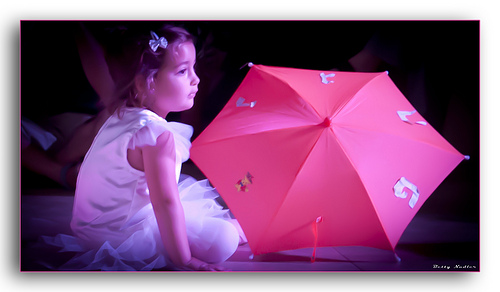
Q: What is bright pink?
A: Umbrella.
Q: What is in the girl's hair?
A: Barrette.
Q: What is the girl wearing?
A: Tutu.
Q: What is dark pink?
A: Umbrella.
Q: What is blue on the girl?
A: Hair ribbon.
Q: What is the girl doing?
A: Sitting.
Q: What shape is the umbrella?
A: Hexagon.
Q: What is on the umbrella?
A: Stickers.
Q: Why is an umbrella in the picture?
A: For effect.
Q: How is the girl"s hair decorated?
A: With a ribbon.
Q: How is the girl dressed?
A: In a dress.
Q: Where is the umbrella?
A: Next to the girl.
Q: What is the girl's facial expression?
A: Somber.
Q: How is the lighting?
A: Dark.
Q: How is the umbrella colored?
A: Pink.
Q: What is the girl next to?
A: An umbrella.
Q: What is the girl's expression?
A: Blank.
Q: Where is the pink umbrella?
A: On the right.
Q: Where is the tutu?
A: On the little girl.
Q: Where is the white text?
A: Bottom right.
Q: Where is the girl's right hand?
A: On the ground.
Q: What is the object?
A: Umbrella.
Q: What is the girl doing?
A: Sitting for pose.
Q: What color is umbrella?
A: Pink.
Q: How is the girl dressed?
A: In a tutu.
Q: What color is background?
A: Black.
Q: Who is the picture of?
A: Girl.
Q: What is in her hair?
A: Hair Bow.